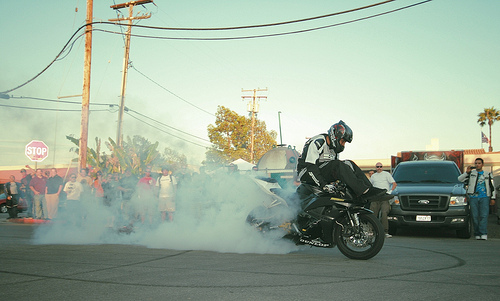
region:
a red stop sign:
[18, 129, 61, 168]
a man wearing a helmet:
[281, 97, 424, 233]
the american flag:
[467, 117, 494, 149]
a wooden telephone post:
[220, 70, 279, 193]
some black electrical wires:
[146, 19, 312, 59]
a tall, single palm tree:
[457, 96, 499, 155]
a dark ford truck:
[374, 112, 486, 257]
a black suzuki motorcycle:
[226, 149, 408, 268]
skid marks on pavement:
[401, 216, 476, 286]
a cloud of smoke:
[43, 155, 304, 276]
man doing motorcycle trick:
[192, 109, 379, 264]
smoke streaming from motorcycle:
[80, 146, 317, 273]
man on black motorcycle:
[157, 123, 422, 287]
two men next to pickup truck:
[375, 148, 499, 220]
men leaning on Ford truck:
[360, 150, 498, 250]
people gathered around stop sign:
[22, 135, 156, 224]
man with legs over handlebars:
[278, 119, 398, 249]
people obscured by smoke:
[55, 155, 241, 261]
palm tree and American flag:
[395, 85, 499, 158]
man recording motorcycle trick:
[450, 142, 498, 222]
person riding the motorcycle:
[293, 118, 393, 204]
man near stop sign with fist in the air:
[17, 164, 34, 193]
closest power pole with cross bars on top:
[108, 1, 155, 176]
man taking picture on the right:
[456, 158, 496, 240]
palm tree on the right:
[477, 106, 499, 155]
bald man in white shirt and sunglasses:
[368, 160, 395, 239]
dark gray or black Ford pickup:
[388, 160, 473, 237]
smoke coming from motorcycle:
[23, 140, 302, 256]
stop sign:
[24, 139, 48, 162]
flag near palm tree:
[479, 130, 488, 146]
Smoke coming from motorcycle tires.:
[72, 184, 265, 249]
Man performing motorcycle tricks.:
[286, 112, 398, 261]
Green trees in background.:
[208, 98, 291, 173]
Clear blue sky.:
[346, 27, 498, 102]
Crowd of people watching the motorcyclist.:
[6, 169, 241, 225]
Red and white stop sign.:
[23, 126, 57, 216]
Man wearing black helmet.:
[293, 122, 397, 254]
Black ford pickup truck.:
[393, 149, 474, 244]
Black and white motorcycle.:
[269, 185, 393, 252]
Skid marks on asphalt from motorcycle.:
[15, 254, 212, 299]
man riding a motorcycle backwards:
[247, 115, 397, 272]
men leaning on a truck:
[365, 157, 493, 237]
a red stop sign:
[22, 135, 49, 165]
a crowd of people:
[5, 165, 192, 230]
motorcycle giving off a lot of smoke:
[44, 112, 404, 268]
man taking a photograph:
[456, 157, 498, 244]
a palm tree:
[469, 97, 499, 146]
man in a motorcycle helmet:
[295, 114, 392, 214]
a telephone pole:
[237, 83, 274, 154]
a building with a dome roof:
[250, 137, 310, 172]